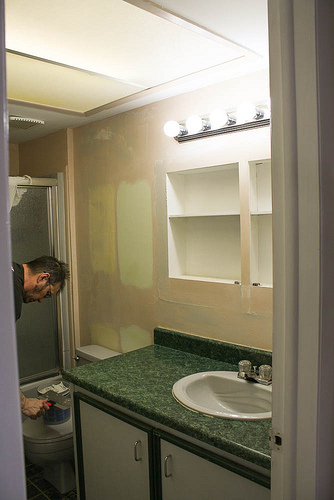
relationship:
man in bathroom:
[12, 256, 70, 420] [4, 0, 270, 499]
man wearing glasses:
[12, 256, 70, 420] [43, 270, 53, 301]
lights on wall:
[163, 97, 271, 143] [71, 70, 272, 352]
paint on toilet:
[39, 380, 71, 426] [23, 345, 122, 493]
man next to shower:
[12, 256, 70, 420] [7, 143, 70, 388]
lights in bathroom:
[163, 97, 271, 143] [4, 0, 270, 499]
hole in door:
[273, 434, 282, 447] [269, 1, 294, 499]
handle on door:
[132, 439, 142, 462] [77, 401, 151, 500]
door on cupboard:
[77, 401, 151, 500] [78, 401, 270, 500]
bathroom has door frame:
[4, 0, 270, 499] [269, 2, 316, 498]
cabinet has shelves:
[165, 159, 275, 287] [167, 212, 272, 220]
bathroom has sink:
[4, 0, 270, 499] [173, 371, 272, 419]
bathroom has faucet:
[4, 0, 270, 499] [237, 371, 274, 386]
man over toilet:
[12, 256, 70, 420] [23, 345, 122, 493]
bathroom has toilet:
[4, 0, 270, 499] [23, 345, 122, 493]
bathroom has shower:
[4, 0, 270, 499] [7, 143, 70, 388]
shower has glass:
[7, 143, 70, 388] [8, 188, 61, 386]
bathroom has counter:
[4, 0, 270, 499] [62, 329, 272, 470]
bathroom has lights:
[4, 0, 270, 499] [163, 97, 271, 143]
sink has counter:
[173, 371, 272, 419] [62, 329, 272, 470]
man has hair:
[12, 256, 70, 420] [24, 256, 68, 292]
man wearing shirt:
[12, 256, 70, 420] [13, 263, 24, 321]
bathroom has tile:
[4, 0, 270, 499] [28, 466, 76, 500]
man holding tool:
[12, 256, 70, 420] [45, 399, 56, 409]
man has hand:
[12, 256, 70, 420] [19, 392, 48, 419]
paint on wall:
[87, 179, 153, 354] [71, 70, 272, 352]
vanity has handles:
[64, 325, 271, 499] [134, 440, 171, 478]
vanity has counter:
[64, 325, 271, 499] [62, 329, 272, 470]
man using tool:
[12, 256, 70, 420] [45, 399, 56, 409]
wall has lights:
[71, 70, 272, 352] [163, 97, 271, 143]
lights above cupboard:
[163, 97, 271, 143] [78, 401, 270, 500]